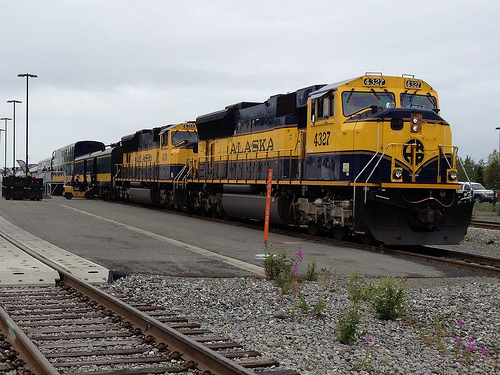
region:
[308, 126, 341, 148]
the black number 4327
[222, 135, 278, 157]
the black word alaska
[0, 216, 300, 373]
these are train tracks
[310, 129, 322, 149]
the black number 4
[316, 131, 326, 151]
the black number 3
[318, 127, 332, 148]
the black number 2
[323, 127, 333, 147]
the black number 7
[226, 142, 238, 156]
the black letter A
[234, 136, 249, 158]
the black letter L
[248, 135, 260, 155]
the black letter S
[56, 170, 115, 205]
Man loading the train with a forklift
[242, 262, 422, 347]
Weeds growing through the gravel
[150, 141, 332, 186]
Railing for walking along the side of the train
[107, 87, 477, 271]
I assume this train is from Alaska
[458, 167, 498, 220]
Parking lot partially hidden by the train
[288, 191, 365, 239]
Some of the many gears that assist in this trains operation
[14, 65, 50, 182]
Light poles to light the station at night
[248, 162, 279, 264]
Fluorescent warning sign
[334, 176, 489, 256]
Super bumper, probably withstands 1000% more impact than a car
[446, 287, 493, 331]
Millions of rocks line the grounds around a train station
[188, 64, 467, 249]
a yellow and black train engine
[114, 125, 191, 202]
a yellow and black train engine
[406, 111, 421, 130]
a train center headlight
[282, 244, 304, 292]
a small purple flower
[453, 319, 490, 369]
a small purple flower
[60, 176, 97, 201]
a small yellow vehicle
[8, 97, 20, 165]
tall overhead street lighting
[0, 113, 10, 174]
tall overhead street lighting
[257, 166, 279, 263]
a plastic orange stick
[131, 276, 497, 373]
a grey gravel bed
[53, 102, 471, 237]
the train is black and yellow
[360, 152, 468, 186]
the head lights are off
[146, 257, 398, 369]
the gravel is grey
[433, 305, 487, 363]
purple flowers are growing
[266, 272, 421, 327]
grass is growing in the gravel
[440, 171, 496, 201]
parked cars by the train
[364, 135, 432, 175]
a round black symbol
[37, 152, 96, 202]
a man on an orange vehicle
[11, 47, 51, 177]
light on a tall pole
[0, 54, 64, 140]
the lights are off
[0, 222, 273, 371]
a set of railroad tracks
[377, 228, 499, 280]
a set of railroad tracks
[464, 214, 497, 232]
a set of railroad tracks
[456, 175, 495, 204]
a parked silver SUV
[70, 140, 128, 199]
a yellow and black passenger car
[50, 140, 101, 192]
a yellow and black train car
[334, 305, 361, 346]
a small patch of green grass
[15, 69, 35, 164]
tall overhead street light